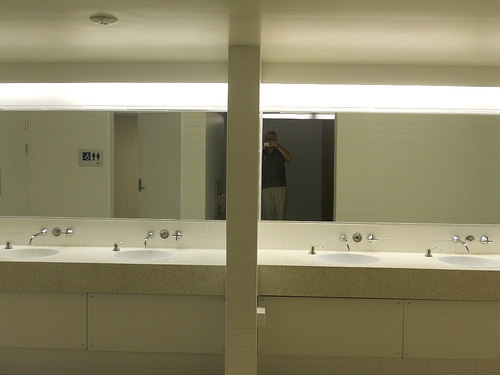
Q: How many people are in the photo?
A: One.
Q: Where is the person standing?
A: Stall.